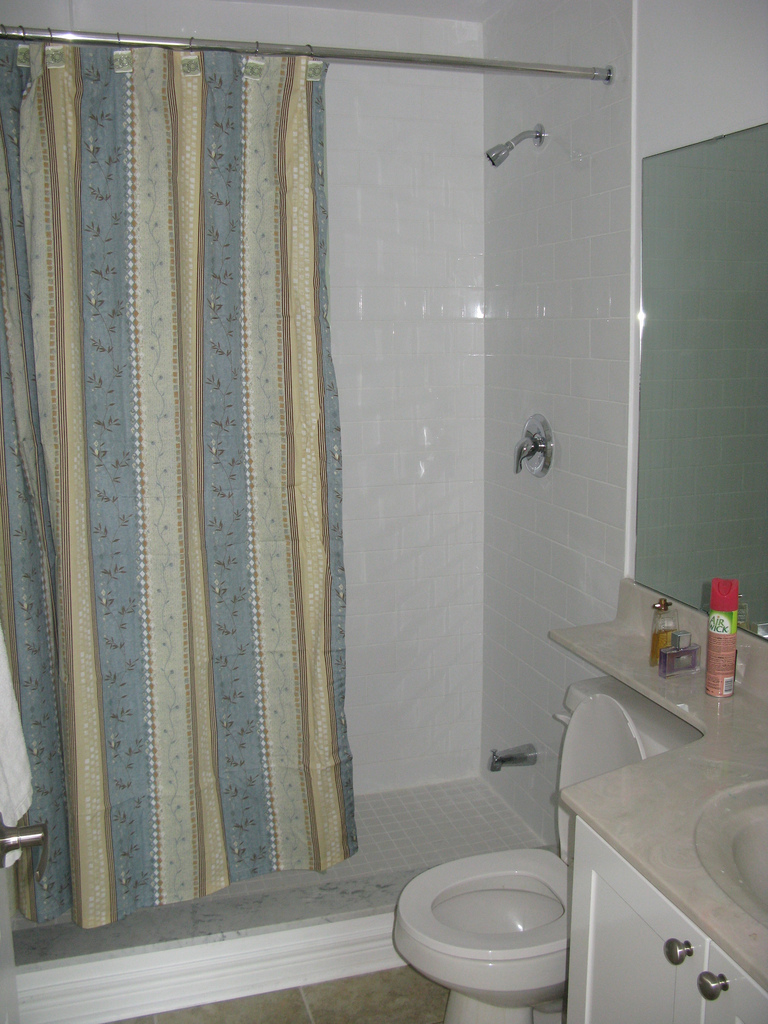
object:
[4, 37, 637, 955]
shower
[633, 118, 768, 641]
mirror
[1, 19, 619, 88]
curtain rod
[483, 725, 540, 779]
faucet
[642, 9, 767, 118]
wall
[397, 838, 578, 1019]
toilet bowl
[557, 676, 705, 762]
tank lid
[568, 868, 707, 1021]
doors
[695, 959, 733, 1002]
knobs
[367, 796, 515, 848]
shower floor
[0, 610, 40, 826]
towel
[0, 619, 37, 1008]
door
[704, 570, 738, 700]
air freshener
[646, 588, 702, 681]
purfume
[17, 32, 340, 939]
shower curtain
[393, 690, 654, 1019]
toilet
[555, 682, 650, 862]
lid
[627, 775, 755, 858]
marble counter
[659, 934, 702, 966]
handles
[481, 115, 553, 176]
shower head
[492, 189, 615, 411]
wall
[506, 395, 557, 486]
faucet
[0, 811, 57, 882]
handle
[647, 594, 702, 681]
bottles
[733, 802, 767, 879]
sink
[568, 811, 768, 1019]
cabinet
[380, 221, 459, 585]
wall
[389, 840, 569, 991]
seat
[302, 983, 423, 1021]
floor